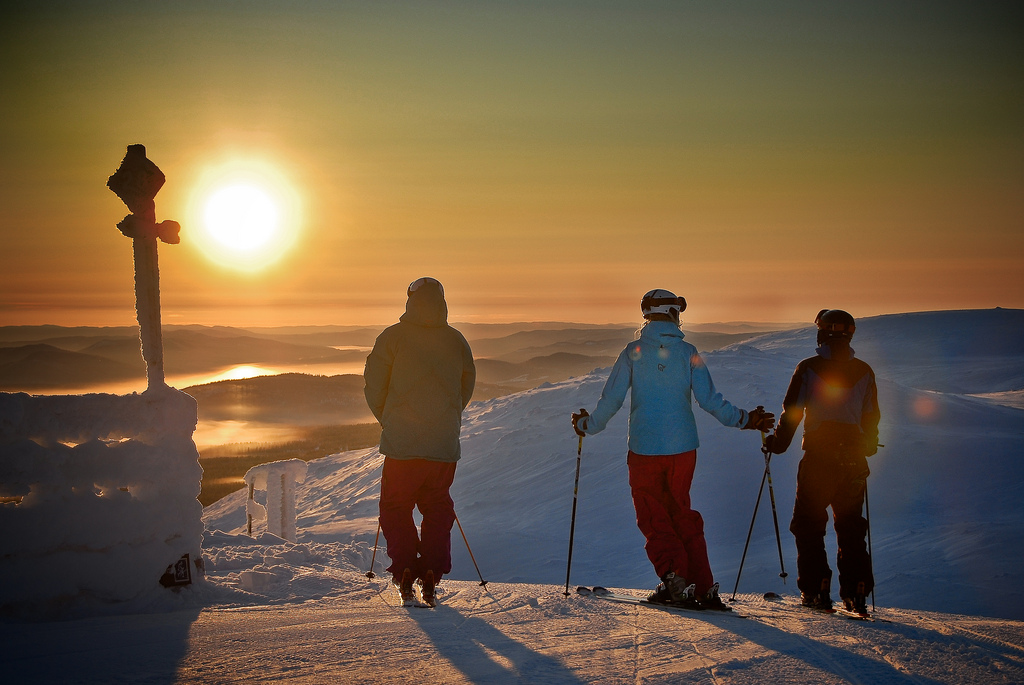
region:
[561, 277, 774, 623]
The skier in the middle is wearing a blue coat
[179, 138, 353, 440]
The sun setting over the mountains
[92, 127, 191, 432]
A pole in the snow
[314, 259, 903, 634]
The skiers are watching the sunset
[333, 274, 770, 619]
The two left most skiers have red pants on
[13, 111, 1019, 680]
the photo is taken at sunset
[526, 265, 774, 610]
The skier in the middle has goggles on her head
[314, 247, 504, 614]
the left skier has his hands in his pockets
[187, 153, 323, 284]
the sun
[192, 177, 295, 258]
the sun is yellow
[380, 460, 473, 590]
person wearing pants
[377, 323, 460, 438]
a sweater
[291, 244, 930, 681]
Group of skiers watching the sun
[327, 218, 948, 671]
Group of skiers watching sunrise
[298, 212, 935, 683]
Group of skiers with ski poles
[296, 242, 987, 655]
Group of skiers on snow packed ridge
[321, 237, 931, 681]
Group of skiers standing on ridge line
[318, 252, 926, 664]
Group of skiers getting ready for run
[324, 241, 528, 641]
Skier with red pants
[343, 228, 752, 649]
Two skiers with red pants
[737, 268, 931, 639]
Skier dressed in black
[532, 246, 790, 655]
Skier with blue jacket and red pants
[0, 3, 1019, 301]
glowing sun in sky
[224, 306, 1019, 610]
snow cover on mountain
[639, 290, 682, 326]
helmet on person's head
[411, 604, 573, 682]
shadow of legs on snow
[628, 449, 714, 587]
snow pants on legs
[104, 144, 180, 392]
sign covered in snow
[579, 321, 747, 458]
back of hooded jacket